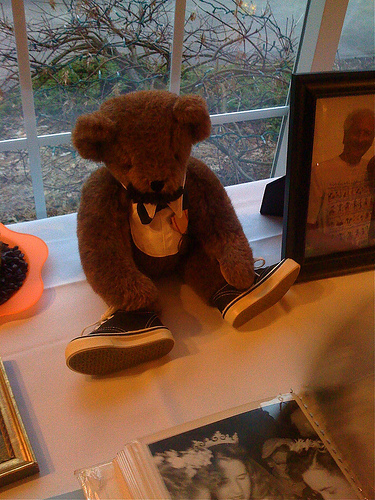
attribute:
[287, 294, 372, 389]
tabletop — Brown  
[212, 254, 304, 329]
shoes — Blue , canvas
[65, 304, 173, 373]
shoes — Blue , canvas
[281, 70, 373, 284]
photo — framed 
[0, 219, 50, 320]
bowl — orange 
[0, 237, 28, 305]
stones — black 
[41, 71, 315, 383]
bear — brown , teddy 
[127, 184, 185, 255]
tuxedo bib — tuxedo 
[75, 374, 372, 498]
album — photo 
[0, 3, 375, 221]
window — no , curtains 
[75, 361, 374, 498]
photo album — photo , Open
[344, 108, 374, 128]
hair — gray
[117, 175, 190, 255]
bib — white, bear's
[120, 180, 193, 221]
bowtie — bear's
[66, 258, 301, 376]
tennis shoe — tennis  , white , black , bear's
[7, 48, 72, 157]
framing — white 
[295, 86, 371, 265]
white picture — stack, black 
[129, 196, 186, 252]
shirt — white 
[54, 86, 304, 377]
teddy bear — teddy 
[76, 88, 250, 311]
teddy bear — teddy 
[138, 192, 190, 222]
tie — bow 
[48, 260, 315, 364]
shoes — canvas 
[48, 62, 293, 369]
bear — teddy 